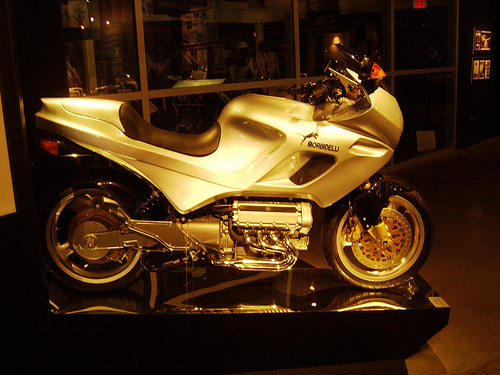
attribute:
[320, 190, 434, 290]
tire — grey, silver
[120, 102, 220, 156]
seat — black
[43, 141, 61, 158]
light — red, reflecting, orange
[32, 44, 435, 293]
motorcycle — display, golden, parked, chrome, leather, silver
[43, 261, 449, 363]
platform — black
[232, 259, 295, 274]
pipe — exposed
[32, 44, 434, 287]
bike — silver